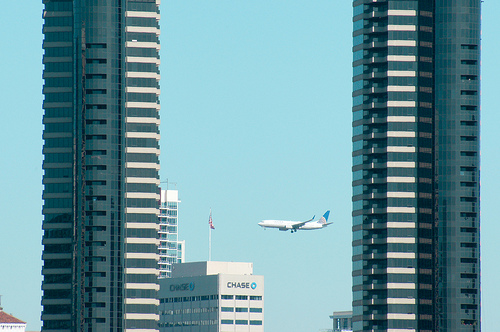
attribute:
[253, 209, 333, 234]
aircraft — large, white, metal, big, flying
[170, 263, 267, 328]
building — white